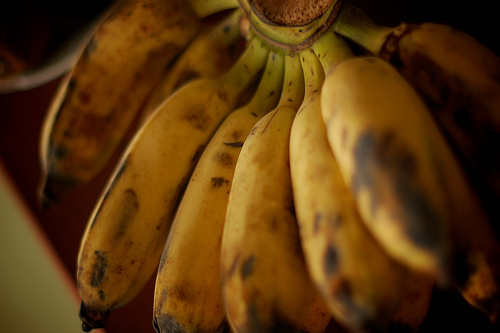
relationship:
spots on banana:
[334, 122, 458, 252] [308, 51, 489, 285]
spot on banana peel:
[344, 117, 456, 269] [317, 78, 497, 275]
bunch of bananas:
[106, 44, 415, 266] [68, 57, 480, 315]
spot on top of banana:
[287, 131, 449, 247] [312, 35, 499, 313]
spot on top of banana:
[304, 256, 375, 319] [293, 62, 495, 332]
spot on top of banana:
[303, 224, 357, 293] [310, 73, 430, 267]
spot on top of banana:
[351, 126, 438, 235] [306, 113, 444, 272]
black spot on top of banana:
[55, 78, 90, 106] [311, 101, 436, 254]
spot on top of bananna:
[342, 135, 453, 252] [66, 7, 498, 294]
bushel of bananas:
[120, 48, 481, 272] [40, 6, 497, 331]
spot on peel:
[327, 127, 438, 237] [342, 122, 456, 276]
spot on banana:
[327, 127, 438, 237] [333, 102, 449, 282]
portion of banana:
[117, 137, 225, 267] [74, 34, 239, 331]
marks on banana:
[300, 212, 369, 305] [287, 46, 437, 325]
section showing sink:
[18, 17, 99, 226] [1, 4, 116, 89]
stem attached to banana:
[199, 3, 348, 62] [317, 30, 484, 297]